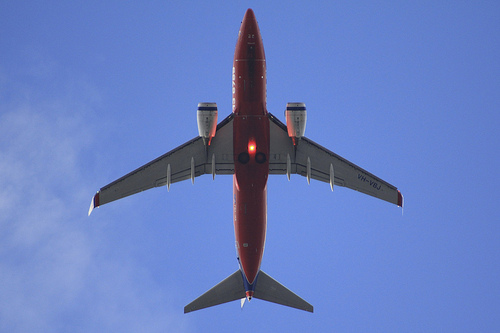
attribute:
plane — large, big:
[87, 7, 409, 315]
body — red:
[232, 9, 269, 280]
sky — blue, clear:
[2, 2, 499, 332]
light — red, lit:
[245, 134, 260, 163]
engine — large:
[284, 98, 310, 153]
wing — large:
[84, 114, 235, 215]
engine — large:
[193, 98, 222, 153]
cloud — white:
[1, 82, 197, 331]